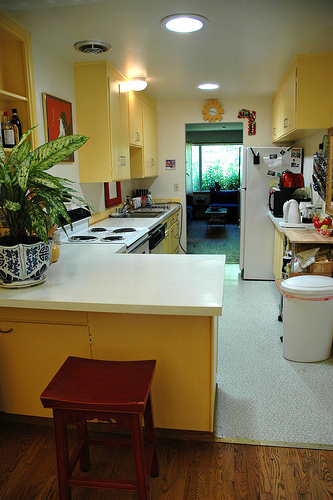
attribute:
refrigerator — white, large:
[235, 142, 303, 282]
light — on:
[165, 16, 204, 33]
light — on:
[196, 83, 218, 91]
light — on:
[129, 77, 147, 93]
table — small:
[203, 204, 230, 238]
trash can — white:
[276, 271, 332, 367]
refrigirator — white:
[241, 145, 296, 280]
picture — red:
[33, 86, 78, 170]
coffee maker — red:
[277, 170, 304, 190]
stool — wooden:
[39, 354, 161, 498]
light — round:
[141, 6, 221, 49]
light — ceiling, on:
[198, 82, 218, 90]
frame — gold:
[39, 86, 59, 97]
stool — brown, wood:
[37, 350, 171, 494]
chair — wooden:
[40, 353, 157, 499]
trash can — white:
[279, 273, 331, 362]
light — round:
[164, 7, 243, 35]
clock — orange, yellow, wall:
[198, 97, 227, 123]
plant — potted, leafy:
[0, 123, 93, 288]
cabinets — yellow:
[76, 63, 163, 183]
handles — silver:
[115, 151, 131, 168]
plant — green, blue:
[0, 125, 90, 241]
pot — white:
[0, 228, 52, 290]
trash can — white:
[259, 249, 330, 348]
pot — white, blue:
[1, 239, 53, 290]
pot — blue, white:
[0, 229, 58, 286]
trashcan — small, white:
[276, 268, 330, 365]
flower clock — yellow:
[202, 96, 225, 122]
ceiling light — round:
[155, 8, 214, 37]